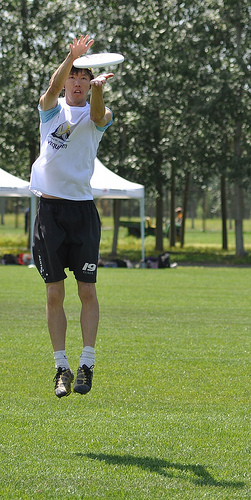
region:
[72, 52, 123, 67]
the frisbee in mid air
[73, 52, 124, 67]
the frisbee is white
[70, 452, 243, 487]
the shadow on the grass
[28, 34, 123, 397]
the man trying to catch the frisbee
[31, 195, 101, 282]
the shorts on the man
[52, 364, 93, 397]
the shoes on the man's feet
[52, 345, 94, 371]
the socks on the man's feet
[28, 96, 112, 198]
the short sleeved shirt on the man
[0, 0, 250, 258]
the trees behind the man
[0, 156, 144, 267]
the white tents behind the man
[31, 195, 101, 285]
Black shirt on a man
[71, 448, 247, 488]
Shadow cast along the green grass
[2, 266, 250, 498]
A field of dark green grass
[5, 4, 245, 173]
Dark green leaves of multiple trees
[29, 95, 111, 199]
The white shirt on a man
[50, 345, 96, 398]
Athletic shoes and white socks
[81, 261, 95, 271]
Numbers on a man's shorts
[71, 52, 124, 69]
Frisbee flying through the air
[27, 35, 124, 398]
Man leaping to catch a Frisbee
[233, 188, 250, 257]
Trunk of a tree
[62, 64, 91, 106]
Man with a look of concentration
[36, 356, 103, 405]
Black and gold cleats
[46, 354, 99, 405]
Man's feet off the ground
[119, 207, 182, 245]
Green and yellow tractor behind trees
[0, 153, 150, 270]
Two white canopies behind frisbee player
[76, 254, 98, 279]
Number 19 on man's shorts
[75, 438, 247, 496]
Shadow of frisbee player on grass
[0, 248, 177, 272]
Backpacks placed on ground by canopies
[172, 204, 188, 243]
Person in yellow standing near tractor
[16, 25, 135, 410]
A man catching a frisbee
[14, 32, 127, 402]
A man catching a frisbee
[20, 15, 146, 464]
an Asian man jumping up to catch of Frisbee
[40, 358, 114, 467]
the feet of a man off of the ground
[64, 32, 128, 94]
two hands catching a frisbee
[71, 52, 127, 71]
a white frisbee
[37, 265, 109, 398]
the legs of a man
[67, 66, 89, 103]
the head of a man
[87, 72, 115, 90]
the hand of a man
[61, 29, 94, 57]
the hand of a man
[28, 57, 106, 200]
a man wearing a white and blue t-shirt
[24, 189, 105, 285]
a pair of black shorts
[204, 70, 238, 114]
green leaves on the tree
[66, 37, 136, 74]
Frisbee in the air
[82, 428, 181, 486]
shadow on the ground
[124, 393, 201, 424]
grass on the ground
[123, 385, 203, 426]
green grass on ground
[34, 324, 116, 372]
socks on the feet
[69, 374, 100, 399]
tip of the shoe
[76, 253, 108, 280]
number on the shorts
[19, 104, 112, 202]
shirt on the person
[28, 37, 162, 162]
man catching a Frisbee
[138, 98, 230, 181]
trees in the distance